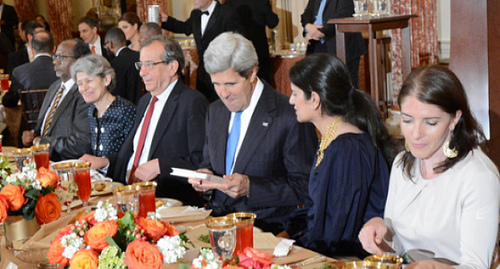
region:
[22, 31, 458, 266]
This is a political dinner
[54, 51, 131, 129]
The woman is smiling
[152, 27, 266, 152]
The man is John Kerry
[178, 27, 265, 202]
John Kerry is holding a book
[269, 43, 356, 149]
The woman is looking at John Kerry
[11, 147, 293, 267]
There are orange roses on the table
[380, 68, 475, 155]
The woman is looking down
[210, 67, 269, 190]
John Kerry has a blue tie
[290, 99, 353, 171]
The woman has a gold necklace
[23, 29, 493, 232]
The people are in a row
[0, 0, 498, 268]
people at a dinner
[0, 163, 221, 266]
floral bouquet center pieces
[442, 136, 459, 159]
large white earring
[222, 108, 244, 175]
a long light blue tie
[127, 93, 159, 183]
a long red tie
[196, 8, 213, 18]
a black bow tie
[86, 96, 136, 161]
a navy blue shirt with white polka dots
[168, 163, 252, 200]
a book in hands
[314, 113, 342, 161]
a thick gold necklace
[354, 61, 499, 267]
brunette woman in white shirt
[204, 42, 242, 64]
man has grey hair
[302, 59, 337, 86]
woman has black hair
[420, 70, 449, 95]
woman has brown hair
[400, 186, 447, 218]
woman wearing white shirt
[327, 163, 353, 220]
woman wearing blue shirt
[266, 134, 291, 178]
man wearing pin stripe jacket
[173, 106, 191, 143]
man wearing black jacket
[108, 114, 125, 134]
woman wearing blue dress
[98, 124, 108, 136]
white button on dress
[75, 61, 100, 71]
woman has grey hair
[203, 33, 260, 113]
secretary of state John Kerry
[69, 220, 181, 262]
flower arrangement on table at dinner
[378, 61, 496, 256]
woman in white blouse at a dinner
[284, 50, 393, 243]
woman in dark hair at a dinner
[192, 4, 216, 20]
bow tie on a man at a dinner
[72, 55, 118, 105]
face of a woman with grey hair at a dinner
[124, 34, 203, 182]
a man with glasses and a red tie at a dinner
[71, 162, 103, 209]
drinks on table being served at a dinner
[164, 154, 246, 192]
a book being held by John Kerry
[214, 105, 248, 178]
blue tie worn by John Kerry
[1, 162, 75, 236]
peach flowers are visible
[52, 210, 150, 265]
peach flowers are visible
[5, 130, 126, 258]
peach flowers are visible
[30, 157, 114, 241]
peach flowers are visible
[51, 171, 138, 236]
peach flowers are visible